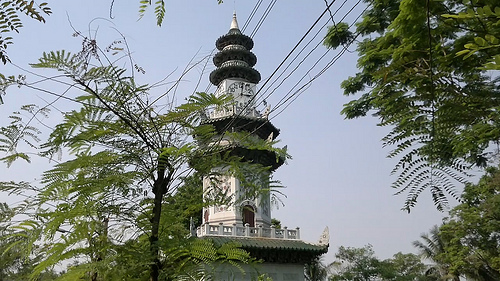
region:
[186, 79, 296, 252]
a white and gray temple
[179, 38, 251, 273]
a white and gray temple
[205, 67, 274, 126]
the clock face is white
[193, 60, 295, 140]
the clock face is white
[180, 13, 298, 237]
white and black tower on building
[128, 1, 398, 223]
power lines running behind building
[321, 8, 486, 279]
trees on right side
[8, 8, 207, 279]
trees on left side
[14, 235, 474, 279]
trees behind white and black tower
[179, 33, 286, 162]
black rings around tower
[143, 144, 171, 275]
trunk of tree on the left side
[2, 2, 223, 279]
leaves of trees on the left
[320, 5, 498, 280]
leaves of trees on the right side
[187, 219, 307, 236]
white railing around lower level of tower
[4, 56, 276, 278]
a leafy green tree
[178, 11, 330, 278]
a white tower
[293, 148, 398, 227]
a clear blue sky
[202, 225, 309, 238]
a railing on a building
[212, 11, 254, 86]
a top of a tower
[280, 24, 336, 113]
gray black power lines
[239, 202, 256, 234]
a brown wooden door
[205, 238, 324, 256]
a clay green roof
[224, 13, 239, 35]
the ponit of a tower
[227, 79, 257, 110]
a clock on the tower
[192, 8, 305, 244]
a white clock tower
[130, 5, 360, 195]
two sets of power lines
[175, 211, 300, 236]
a white railing in front of a balcony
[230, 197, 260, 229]
a door on the tower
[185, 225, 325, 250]
shingles on a roof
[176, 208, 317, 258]
a white railing above shingles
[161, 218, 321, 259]
shingles below a white railing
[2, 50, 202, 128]
power lines behind trees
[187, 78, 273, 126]
a white railing surrounding the clock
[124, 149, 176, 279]
a narrow trunk from a tree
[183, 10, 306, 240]
A tower in the photo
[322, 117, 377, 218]
Blue sky in the photo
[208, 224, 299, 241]
A balcony in the photo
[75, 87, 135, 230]
Leaves in the photo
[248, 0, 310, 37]
Cables in the photo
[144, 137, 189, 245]
A tree in the photo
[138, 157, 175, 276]
A tree in the photo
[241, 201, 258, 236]
A door in the photo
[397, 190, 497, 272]
Trees in the photo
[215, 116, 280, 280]
A building in the photo